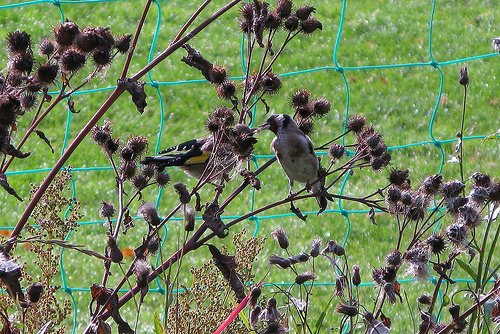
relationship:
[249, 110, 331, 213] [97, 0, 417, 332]
bird sitting on branch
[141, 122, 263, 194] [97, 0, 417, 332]
bird sitting on branch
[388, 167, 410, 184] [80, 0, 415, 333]
flower on plant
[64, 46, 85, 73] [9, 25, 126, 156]
flower on plant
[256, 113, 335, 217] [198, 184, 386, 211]
bird standing on branch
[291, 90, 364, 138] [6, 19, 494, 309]
flower on plant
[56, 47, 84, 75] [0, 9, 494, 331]
flower on plant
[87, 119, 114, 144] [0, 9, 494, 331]
flower on plant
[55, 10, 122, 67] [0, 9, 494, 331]
purple flower on plant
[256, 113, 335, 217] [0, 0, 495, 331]
bird sitting on fence